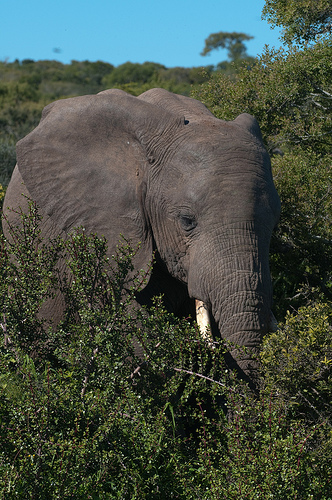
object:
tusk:
[192, 297, 215, 354]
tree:
[198, 30, 255, 58]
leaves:
[0, 3, 331, 498]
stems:
[61, 242, 75, 261]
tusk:
[206, 289, 267, 428]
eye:
[178, 211, 197, 233]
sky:
[0, 0, 331, 66]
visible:
[0, 193, 331, 498]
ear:
[16, 93, 153, 293]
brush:
[0, 0, 330, 498]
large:
[15, 103, 154, 295]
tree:
[259, 1, 329, 49]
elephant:
[0, 87, 282, 444]